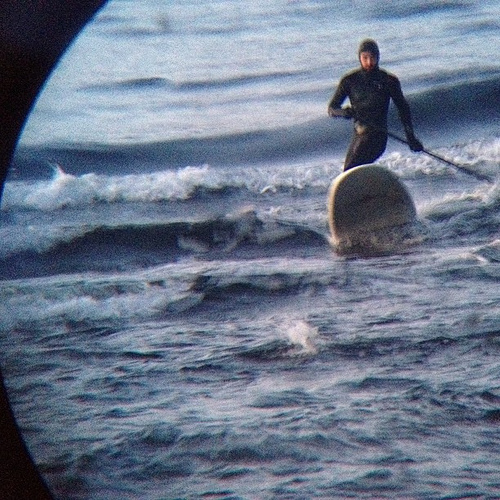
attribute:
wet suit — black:
[331, 30, 434, 166]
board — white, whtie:
[321, 160, 405, 234]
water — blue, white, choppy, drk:
[128, 43, 164, 68]